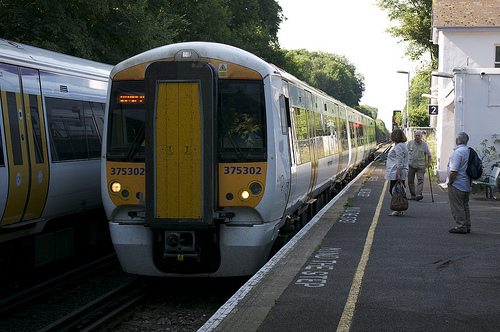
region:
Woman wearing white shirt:
[383, 120, 410, 220]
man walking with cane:
[406, 129, 436, 207]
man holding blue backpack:
[443, 128, 484, 240]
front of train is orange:
[105, 49, 270, 234]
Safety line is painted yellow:
[330, 175, 397, 329]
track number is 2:
[422, 98, 446, 123]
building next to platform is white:
[428, 4, 498, 166]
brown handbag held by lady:
[389, 176, 412, 218]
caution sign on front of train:
[214, 60, 230, 83]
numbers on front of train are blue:
[218, 162, 268, 177]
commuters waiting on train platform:
[371, 124, 484, 218]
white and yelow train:
[101, 24, 401, 257]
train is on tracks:
[82, 26, 231, 318]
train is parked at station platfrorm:
[206, 24, 368, 280]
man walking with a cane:
[408, 131, 438, 205]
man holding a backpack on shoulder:
[446, 139, 479, 231]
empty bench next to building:
[471, 162, 498, 201]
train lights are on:
[105, 175, 262, 205]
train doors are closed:
[7, 81, 47, 228]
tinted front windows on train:
[121, 72, 244, 162]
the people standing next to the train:
[383, 123, 479, 243]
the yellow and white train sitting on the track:
[103, 37, 383, 293]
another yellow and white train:
[0, 37, 110, 239]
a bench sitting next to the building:
[471, 166, 498, 192]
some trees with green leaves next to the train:
[2, 2, 392, 117]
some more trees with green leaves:
[376, 2, 432, 129]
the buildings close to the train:
[428, 2, 498, 179]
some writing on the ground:
[303, 202, 365, 298]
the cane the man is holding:
[421, 162, 439, 204]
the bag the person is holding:
[386, 180, 410, 215]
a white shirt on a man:
[446, 142, 471, 190]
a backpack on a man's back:
[467, 143, 485, 180]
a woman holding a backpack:
[385, 125, 410, 216]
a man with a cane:
[408, 125, 437, 203]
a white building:
[417, 2, 499, 184]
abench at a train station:
[473, 163, 499, 196]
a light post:
[392, 63, 416, 140]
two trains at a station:
[1, 18, 388, 288]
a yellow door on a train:
[149, 75, 221, 230]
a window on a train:
[218, 75, 272, 166]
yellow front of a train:
[104, 53, 270, 210]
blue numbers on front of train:
[220, 163, 264, 178]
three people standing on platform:
[382, 127, 486, 234]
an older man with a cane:
[406, 128, 436, 202]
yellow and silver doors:
[0, 63, 50, 232]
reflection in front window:
[215, 85, 261, 155]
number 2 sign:
[426, 102, 436, 113]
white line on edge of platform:
[198, 158, 373, 328]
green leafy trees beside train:
[1, 0, 380, 116]